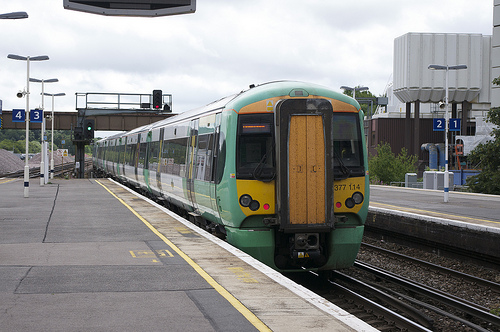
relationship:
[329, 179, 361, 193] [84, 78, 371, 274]
numbers on front of train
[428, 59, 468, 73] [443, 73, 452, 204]
light on pole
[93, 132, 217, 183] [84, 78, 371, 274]
windows on train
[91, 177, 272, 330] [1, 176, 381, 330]
stripe on platform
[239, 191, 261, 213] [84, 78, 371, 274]
light on train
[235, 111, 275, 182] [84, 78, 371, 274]
window on train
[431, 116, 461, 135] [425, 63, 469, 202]
signs on light pole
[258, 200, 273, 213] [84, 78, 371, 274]
light on train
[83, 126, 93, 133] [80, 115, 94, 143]
light on traffic signal